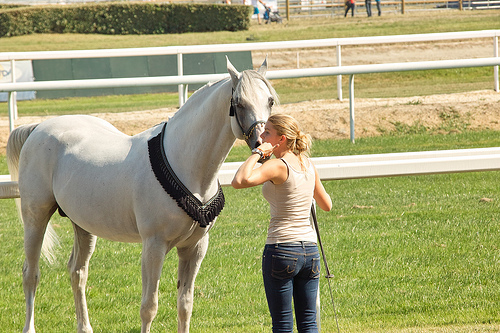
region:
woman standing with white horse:
[7, 38, 344, 328]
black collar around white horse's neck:
[145, 118, 230, 224]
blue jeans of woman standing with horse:
[260, 241, 320, 328]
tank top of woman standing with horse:
[264, 153, 334, 235]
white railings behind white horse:
[4, 39, 499, 164]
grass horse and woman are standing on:
[7, 193, 488, 329]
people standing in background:
[251, 0, 393, 20]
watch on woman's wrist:
[250, 149, 265, 158]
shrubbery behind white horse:
[0, 3, 248, 41]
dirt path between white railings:
[7, 75, 499, 122]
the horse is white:
[24, 72, 289, 322]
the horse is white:
[67, 60, 302, 145]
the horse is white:
[99, 56, 261, 204]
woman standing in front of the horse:
[216, 58, 357, 331]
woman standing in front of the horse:
[148, 24, 400, 316]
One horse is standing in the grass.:
[35, 86, 233, 316]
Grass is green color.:
[372, 202, 467, 283]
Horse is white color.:
[38, 95, 283, 300]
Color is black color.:
[138, 126, 240, 237]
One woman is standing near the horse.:
[227, 119, 338, 306]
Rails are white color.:
[248, 23, 404, 125]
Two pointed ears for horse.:
[214, 54, 284, 89]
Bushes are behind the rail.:
[3, 2, 268, 64]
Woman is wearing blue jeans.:
[253, 238, 328, 330]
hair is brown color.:
[262, 106, 312, 153]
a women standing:
[245, 138, 341, 331]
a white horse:
[20, 58, 252, 331]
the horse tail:
[1, 128, 31, 159]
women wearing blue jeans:
[270, 250, 320, 332]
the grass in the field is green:
[362, 210, 495, 332]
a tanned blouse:
[283, 193, 313, 231]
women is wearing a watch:
[251, 143, 266, 158]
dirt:
[365, 99, 420, 128]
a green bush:
[108, 8, 236, 29]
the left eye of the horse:
[269, 94, 276, 108]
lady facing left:
[234, 113, 329, 331]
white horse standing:
[5, 50, 270, 330]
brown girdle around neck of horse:
[135, 115, 230, 227]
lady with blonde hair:
[251, 110, 311, 155]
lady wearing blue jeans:
[257, 235, 332, 327]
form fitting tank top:
[255, 150, 326, 245]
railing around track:
[310, 30, 495, 111]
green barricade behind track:
[26, 49, 263, 99]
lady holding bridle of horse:
[244, 122, 333, 326]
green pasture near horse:
[344, 190, 469, 319]